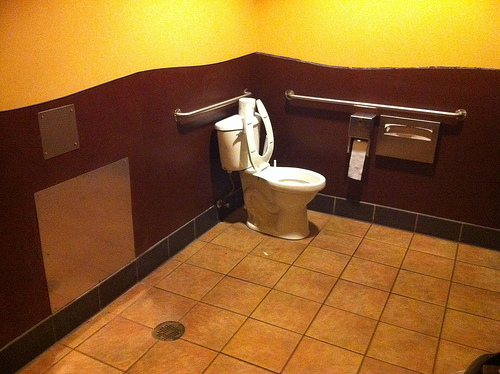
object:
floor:
[155, 254, 330, 351]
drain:
[149, 320, 185, 342]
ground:
[106, 258, 295, 373]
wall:
[60, 19, 135, 88]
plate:
[38, 104, 81, 161]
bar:
[174, 87, 265, 123]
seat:
[244, 98, 275, 174]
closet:
[238, 167, 326, 241]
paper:
[347, 136, 371, 181]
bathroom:
[0, 0, 500, 374]